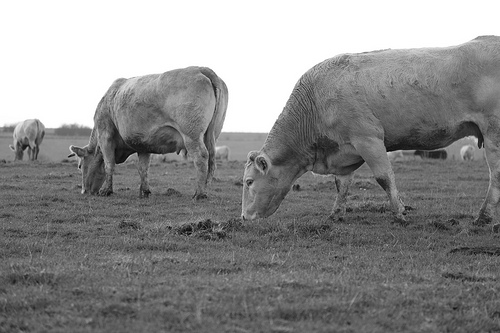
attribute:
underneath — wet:
[381, 125, 475, 157]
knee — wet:
[332, 186, 342, 204]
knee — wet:
[375, 173, 394, 193]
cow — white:
[458, 143, 476, 164]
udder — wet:
[170, 133, 190, 157]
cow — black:
[412, 147, 449, 162]